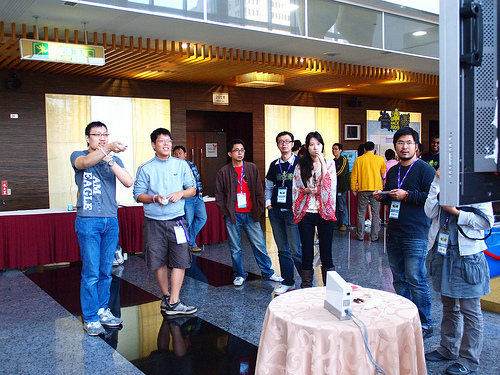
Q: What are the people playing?
A: Wii.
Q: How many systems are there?
A: One.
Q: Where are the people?
A: Lobby.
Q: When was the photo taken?
A: Daytime.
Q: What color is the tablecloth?
A: Pink.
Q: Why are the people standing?
A: To play.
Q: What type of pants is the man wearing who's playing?
A: Jeans.